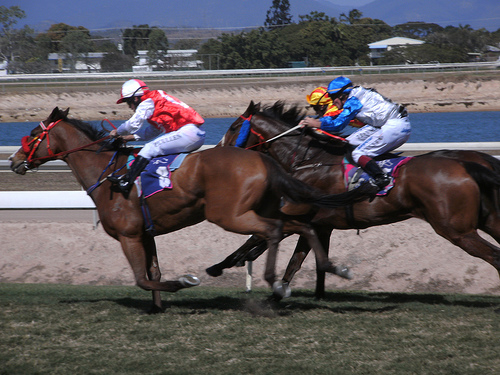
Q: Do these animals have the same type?
A: Yes, all the animals are horses.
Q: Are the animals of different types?
A: No, all the animals are horses.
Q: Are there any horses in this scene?
A: Yes, there is a horse.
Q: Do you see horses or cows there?
A: Yes, there is a horse.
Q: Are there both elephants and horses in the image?
A: No, there is a horse but no elephants.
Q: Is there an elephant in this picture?
A: No, there are no elephants.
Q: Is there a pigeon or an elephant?
A: No, there are no elephants or pigeons.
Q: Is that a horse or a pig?
A: That is a horse.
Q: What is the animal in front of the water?
A: The animal is a horse.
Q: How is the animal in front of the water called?
A: The animal is a horse.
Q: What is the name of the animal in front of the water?
A: The animal is a horse.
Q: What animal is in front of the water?
A: The animal is a horse.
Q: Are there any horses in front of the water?
A: Yes, there is a horse in front of the water.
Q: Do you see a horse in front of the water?
A: Yes, there is a horse in front of the water.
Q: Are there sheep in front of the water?
A: No, there is a horse in front of the water.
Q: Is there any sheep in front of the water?
A: No, there is a horse in front of the water.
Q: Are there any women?
A: No, there are no women.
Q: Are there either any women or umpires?
A: No, there are no women or umpires.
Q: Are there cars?
A: No, there are no cars.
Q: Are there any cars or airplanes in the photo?
A: No, there are no cars or airplanes.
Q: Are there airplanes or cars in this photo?
A: No, there are no cars or airplanes.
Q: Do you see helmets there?
A: Yes, there is a helmet.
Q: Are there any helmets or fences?
A: Yes, there is a helmet.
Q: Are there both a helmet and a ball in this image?
A: No, there is a helmet but no balls.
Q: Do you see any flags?
A: No, there are no flags.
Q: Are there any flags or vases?
A: No, there are no flags or vases.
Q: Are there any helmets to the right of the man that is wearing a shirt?
A: Yes, there is a helmet to the right of the man.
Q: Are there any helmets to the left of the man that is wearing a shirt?
A: No, the helmet is to the right of the man.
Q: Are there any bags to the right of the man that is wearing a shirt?
A: No, there is a helmet to the right of the man.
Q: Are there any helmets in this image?
A: Yes, there is a helmet.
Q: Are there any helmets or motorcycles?
A: Yes, there is a helmet.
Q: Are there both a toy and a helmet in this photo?
A: No, there is a helmet but no toys.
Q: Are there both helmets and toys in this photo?
A: No, there is a helmet but no toys.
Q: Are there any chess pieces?
A: No, there are no chess pieces.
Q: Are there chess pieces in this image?
A: No, there are no chess pieces.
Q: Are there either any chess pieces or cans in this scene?
A: No, there are no chess pieces or cans.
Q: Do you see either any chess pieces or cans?
A: No, there are no chess pieces or cans.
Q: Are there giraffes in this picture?
A: No, there are no giraffes.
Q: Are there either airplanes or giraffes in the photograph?
A: No, there are no giraffes or airplanes.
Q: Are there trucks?
A: No, there are no trucks.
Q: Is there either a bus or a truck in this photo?
A: No, there are no trucks or buses.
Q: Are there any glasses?
A: No, there are no glasses.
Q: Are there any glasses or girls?
A: No, there are no glasses or girls.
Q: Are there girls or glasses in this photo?
A: No, there are no glasses or girls.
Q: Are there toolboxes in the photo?
A: No, there are no toolboxes.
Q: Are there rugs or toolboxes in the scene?
A: No, there are no toolboxes or rugs.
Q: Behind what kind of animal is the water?
A: The water is behind the horse.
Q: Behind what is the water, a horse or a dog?
A: The water is behind a horse.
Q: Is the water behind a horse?
A: Yes, the water is behind a horse.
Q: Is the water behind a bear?
A: No, the water is behind a horse.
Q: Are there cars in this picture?
A: No, there are no cars.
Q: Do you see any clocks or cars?
A: No, there are no cars or clocks.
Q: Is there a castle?
A: No, there are no castles.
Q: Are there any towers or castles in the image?
A: No, there are no castles or towers.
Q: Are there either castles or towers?
A: No, there are no castles or towers.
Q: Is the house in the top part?
A: Yes, the house is in the top of the image.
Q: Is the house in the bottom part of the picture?
A: No, the house is in the top of the image.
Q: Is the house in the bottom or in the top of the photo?
A: The house is in the top of the image.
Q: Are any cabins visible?
A: No, there are no cabins.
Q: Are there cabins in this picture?
A: No, there are no cabins.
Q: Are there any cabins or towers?
A: No, there are no cabins or towers.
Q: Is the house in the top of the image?
A: Yes, the house is in the top of the image.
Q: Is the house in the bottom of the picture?
A: No, the house is in the top of the image.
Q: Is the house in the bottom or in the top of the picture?
A: The house is in the top of the image.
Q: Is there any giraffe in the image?
A: No, there are no giraffes.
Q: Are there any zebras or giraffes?
A: No, there are no giraffes or zebras.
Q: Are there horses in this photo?
A: Yes, there is a horse.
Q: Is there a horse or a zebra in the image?
A: Yes, there is a horse.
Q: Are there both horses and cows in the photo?
A: No, there is a horse but no cows.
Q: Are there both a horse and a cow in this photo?
A: No, there is a horse but no cows.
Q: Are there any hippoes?
A: No, there are no hippoes.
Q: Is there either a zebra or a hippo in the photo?
A: No, there are no hippoes or zebras.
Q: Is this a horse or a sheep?
A: This is a horse.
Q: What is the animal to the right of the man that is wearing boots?
A: The animal is a horse.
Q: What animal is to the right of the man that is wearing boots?
A: The animal is a horse.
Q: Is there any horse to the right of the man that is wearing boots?
A: Yes, there is a horse to the right of the man.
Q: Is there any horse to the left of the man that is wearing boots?
A: No, the horse is to the right of the man.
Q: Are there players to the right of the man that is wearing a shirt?
A: No, there is a horse to the right of the man.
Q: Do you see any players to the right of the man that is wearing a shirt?
A: No, there is a horse to the right of the man.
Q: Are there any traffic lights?
A: No, there are no traffic lights.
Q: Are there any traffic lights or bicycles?
A: No, there are no traffic lights or bicycles.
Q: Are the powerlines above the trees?
A: Yes, the powerlines are above the trees.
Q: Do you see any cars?
A: No, there are no cars.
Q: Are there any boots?
A: Yes, there are boots.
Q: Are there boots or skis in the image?
A: Yes, there are boots.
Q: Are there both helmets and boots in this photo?
A: Yes, there are both boots and a helmet.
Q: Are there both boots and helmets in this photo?
A: Yes, there are both boots and a helmet.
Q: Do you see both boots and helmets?
A: Yes, there are both boots and a helmet.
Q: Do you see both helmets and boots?
A: Yes, there are both boots and a helmet.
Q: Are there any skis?
A: No, there are no skis.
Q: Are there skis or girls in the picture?
A: No, there are no skis or girls.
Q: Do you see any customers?
A: No, there are no customers.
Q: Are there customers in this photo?
A: No, there are no customers.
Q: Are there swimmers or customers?
A: No, there are no customers or swimmers.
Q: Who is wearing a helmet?
A: The man is wearing a helmet.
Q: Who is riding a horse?
A: The man is riding a horse.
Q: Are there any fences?
A: Yes, there is a fence.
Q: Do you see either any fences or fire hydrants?
A: Yes, there is a fence.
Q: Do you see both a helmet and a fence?
A: Yes, there are both a fence and a helmet.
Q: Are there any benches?
A: No, there are no benches.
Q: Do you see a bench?
A: No, there are no benches.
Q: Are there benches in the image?
A: No, there are no benches.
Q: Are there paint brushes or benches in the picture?
A: No, there are no benches or paint brushes.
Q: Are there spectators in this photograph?
A: No, there are no spectators.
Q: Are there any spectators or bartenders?
A: No, there are no spectators or bartenders.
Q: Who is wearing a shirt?
A: The man is wearing a shirt.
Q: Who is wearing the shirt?
A: The man is wearing a shirt.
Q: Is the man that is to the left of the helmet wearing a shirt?
A: Yes, the man is wearing a shirt.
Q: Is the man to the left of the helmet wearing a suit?
A: No, the man is wearing a shirt.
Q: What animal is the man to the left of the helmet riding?
A: The man is riding a horse.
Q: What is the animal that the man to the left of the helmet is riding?
A: The animal is a horse.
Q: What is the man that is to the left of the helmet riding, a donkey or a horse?
A: The man is riding a horse.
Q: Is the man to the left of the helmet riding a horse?
A: Yes, the man is riding a horse.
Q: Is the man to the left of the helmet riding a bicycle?
A: No, the man is riding a horse.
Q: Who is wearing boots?
A: The man is wearing boots.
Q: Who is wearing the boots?
A: The man is wearing boots.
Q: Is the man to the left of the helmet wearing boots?
A: Yes, the man is wearing boots.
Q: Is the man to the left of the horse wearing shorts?
A: No, the man is wearing boots.